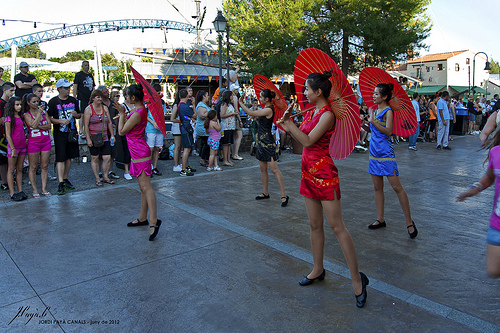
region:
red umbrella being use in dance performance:
[289, 44, 361, 162]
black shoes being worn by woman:
[294, 268, 371, 310]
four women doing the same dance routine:
[110, 43, 420, 310]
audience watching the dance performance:
[4, 61, 498, 201]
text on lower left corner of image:
[6, 306, 124, 325]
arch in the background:
[0, 18, 226, 53]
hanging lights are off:
[3, 17, 216, 32]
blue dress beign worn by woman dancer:
[365, 108, 402, 176]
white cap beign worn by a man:
[54, 75, 76, 91]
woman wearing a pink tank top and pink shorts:
[22, 96, 53, 203]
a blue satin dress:
[366, 108, 399, 181]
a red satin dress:
[297, 102, 344, 204]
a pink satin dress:
[116, 107, 153, 179]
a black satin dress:
[252, 105, 279, 165]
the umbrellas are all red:
[289, 44, 361, 163]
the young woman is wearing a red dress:
[278, 43, 370, 312]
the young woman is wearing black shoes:
[117, 81, 163, 246]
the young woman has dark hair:
[366, 82, 420, 242]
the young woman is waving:
[232, 91, 293, 207]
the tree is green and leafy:
[221, 1, 432, 78]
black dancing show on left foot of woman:
[350, 270, 371, 313]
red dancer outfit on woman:
[299, 107, 341, 199]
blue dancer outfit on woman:
[368, 105, 400, 173]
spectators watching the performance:
[4, 63, 499, 202]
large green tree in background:
[218, 1, 433, 78]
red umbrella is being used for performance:
[292, 48, 360, 162]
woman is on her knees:
[457, 128, 499, 282]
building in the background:
[393, 51, 492, 86]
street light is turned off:
[211, 11, 228, 96]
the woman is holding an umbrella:
[272, 39, 363, 186]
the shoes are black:
[260, 245, 382, 310]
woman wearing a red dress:
[268, 58, 345, 208]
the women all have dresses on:
[78, 46, 430, 232]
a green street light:
[187, 5, 245, 83]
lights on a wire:
[0, 15, 245, 39]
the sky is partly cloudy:
[424, 0, 492, 45]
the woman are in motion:
[68, 62, 451, 243]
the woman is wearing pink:
[12, 85, 56, 189]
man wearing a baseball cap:
[44, 57, 79, 102]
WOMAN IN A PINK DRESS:
[118, 67, 171, 242]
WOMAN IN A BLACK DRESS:
[238, 77, 293, 212]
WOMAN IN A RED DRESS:
[281, 52, 368, 310]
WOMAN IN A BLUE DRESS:
[358, 67, 423, 242]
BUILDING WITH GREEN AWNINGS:
[405, 48, 489, 126]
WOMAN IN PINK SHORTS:
[26, 92, 53, 198]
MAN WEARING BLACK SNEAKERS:
[48, 77, 82, 196]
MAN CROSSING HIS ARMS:
[13, 61, 40, 98]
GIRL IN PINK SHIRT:
[201, 106, 225, 174]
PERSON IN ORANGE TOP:
[424, 92, 440, 144]